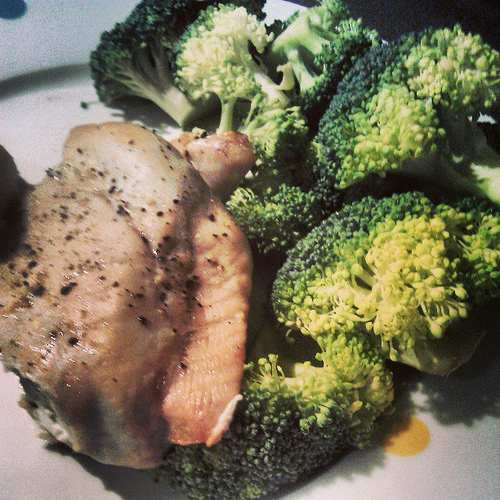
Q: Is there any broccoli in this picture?
A: Yes, there is broccoli.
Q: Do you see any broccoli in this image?
A: Yes, there is broccoli.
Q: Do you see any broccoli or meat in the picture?
A: Yes, there is broccoli.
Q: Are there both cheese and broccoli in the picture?
A: No, there is broccoli but no cheese.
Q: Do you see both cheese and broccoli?
A: No, there is broccoli but no cheese.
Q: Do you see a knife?
A: No, there are no knives.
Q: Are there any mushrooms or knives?
A: No, there are no knives or mushrooms.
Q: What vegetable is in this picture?
A: The vegetable is broccoli.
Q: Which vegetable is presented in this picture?
A: The vegetable is broccoli.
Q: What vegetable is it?
A: The vegetable is broccoli.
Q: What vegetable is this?
A: This is broccoli.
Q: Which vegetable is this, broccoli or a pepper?
A: This is broccoli.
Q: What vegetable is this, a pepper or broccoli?
A: This is broccoli.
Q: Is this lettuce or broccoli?
A: This is broccoli.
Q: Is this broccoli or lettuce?
A: This is broccoli.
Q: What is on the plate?
A: The broccoli is on the plate.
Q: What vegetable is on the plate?
A: The vegetable is broccoli.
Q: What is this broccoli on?
A: The broccoli is on the plate.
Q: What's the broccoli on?
A: The broccoli is on the plate.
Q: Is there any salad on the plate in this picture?
A: No, there is broccoli on the plate.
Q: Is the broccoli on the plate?
A: Yes, the broccoli is on the plate.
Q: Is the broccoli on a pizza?
A: No, the broccoli is on the plate.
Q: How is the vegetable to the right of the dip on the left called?
A: The vegetable is broccoli.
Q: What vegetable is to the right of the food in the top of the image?
A: The vegetable is broccoli.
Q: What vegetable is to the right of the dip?
A: The vegetable is broccoli.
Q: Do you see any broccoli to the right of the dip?
A: Yes, there is broccoli to the right of the dip.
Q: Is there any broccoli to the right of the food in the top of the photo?
A: Yes, there is broccoli to the right of the dip.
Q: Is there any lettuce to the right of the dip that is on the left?
A: No, there is broccoli to the right of the dip.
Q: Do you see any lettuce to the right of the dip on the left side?
A: No, there is broccoli to the right of the dip.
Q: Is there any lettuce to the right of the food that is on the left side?
A: No, there is broccoli to the right of the dip.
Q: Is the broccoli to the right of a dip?
A: Yes, the broccoli is to the right of a dip.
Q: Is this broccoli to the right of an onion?
A: No, the broccoli is to the right of a dip.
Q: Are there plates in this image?
A: Yes, there is a plate.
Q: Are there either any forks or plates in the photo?
A: Yes, there is a plate.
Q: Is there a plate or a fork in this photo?
A: Yes, there is a plate.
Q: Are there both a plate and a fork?
A: No, there is a plate but no forks.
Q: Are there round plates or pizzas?
A: Yes, there is a round plate.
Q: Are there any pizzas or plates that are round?
A: Yes, the plate is round.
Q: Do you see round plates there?
A: Yes, there is a round plate.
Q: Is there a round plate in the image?
A: Yes, there is a round plate.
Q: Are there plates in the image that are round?
A: Yes, there is a plate that is round.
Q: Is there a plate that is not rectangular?
A: Yes, there is a round plate.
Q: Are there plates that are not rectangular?
A: Yes, there is a round plate.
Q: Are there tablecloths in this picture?
A: No, there are no tablecloths.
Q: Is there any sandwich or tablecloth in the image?
A: No, there are no tablecloths or sandwiches.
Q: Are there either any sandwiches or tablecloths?
A: No, there are no tablecloths or sandwiches.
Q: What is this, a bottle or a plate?
A: This is a plate.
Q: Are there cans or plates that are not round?
A: No, there is a plate but it is round.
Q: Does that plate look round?
A: Yes, the plate is round.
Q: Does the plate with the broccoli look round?
A: Yes, the plate is round.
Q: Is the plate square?
A: No, the plate is round.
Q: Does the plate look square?
A: No, the plate is round.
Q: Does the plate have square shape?
A: No, the plate is round.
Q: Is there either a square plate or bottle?
A: No, there is a plate but it is round.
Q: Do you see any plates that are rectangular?
A: No, there is a plate but it is round.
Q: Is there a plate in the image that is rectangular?
A: No, there is a plate but it is round.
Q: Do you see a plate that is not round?
A: No, there is a plate but it is round.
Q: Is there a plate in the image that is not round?
A: No, there is a plate but it is round.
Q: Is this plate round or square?
A: The plate is round.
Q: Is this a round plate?
A: Yes, this is a round plate.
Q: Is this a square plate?
A: No, this is a round plate.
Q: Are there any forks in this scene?
A: No, there are no forks.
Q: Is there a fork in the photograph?
A: No, there are no forks.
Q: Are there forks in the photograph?
A: No, there are no forks.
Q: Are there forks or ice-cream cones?
A: No, there are no forks or ice-cream cones.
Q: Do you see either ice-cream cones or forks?
A: No, there are no forks or ice-cream cones.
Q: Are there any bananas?
A: No, there are no bananas.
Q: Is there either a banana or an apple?
A: No, there are no bananas or apples.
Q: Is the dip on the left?
A: Yes, the dip is on the left of the image.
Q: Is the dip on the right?
A: No, the dip is on the left of the image.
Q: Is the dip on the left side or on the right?
A: The dip is on the left of the image.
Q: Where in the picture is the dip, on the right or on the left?
A: The dip is on the left of the image.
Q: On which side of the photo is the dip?
A: The dip is on the left of the image.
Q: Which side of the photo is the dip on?
A: The dip is on the left of the image.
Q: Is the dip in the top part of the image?
A: Yes, the dip is in the top of the image.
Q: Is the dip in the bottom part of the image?
A: No, the dip is in the top of the image.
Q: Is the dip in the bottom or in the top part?
A: The dip is in the top of the image.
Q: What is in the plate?
A: The dip is in the plate.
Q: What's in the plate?
A: The dip is in the plate.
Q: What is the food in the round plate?
A: The food is a dip.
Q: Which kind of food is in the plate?
A: The food is a dip.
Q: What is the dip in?
A: The dip is in the plate.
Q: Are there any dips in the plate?
A: Yes, there is a dip in the plate.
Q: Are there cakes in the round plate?
A: No, there is a dip in the plate.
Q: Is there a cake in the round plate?
A: No, there is a dip in the plate.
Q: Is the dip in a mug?
A: No, the dip is in the plate.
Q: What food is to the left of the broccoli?
A: The food is a dip.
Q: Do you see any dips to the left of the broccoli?
A: Yes, there is a dip to the left of the broccoli.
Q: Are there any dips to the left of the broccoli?
A: Yes, there is a dip to the left of the broccoli.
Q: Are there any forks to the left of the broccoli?
A: No, there is a dip to the left of the broccoli.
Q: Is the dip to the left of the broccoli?
A: Yes, the dip is to the left of the broccoli.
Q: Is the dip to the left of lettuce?
A: No, the dip is to the left of the broccoli.